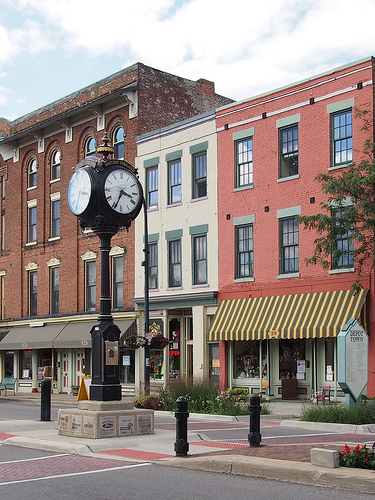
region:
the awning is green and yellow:
[204, 283, 370, 344]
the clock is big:
[62, 156, 146, 233]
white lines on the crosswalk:
[0, 448, 151, 497]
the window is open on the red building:
[272, 116, 303, 183]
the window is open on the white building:
[186, 144, 210, 201]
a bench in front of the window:
[0, 374, 19, 401]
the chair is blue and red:
[311, 382, 335, 406]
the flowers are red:
[339, 441, 366, 465]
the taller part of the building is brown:
[4, 61, 242, 399]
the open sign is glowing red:
[166, 346, 182, 358]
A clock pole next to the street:
[56, 133, 148, 402]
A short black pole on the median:
[170, 393, 195, 461]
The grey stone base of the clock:
[53, 399, 160, 440]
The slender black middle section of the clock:
[89, 224, 119, 322]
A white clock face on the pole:
[104, 168, 139, 216]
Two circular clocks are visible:
[66, 165, 146, 220]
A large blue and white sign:
[334, 311, 373, 402]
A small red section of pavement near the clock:
[104, 445, 174, 464]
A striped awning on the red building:
[213, 295, 366, 338]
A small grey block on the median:
[308, 445, 347, 469]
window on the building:
[188, 148, 217, 210]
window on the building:
[184, 234, 213, 284]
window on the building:
[159, 241, 183, 286]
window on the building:
[142, 246, 155, 288]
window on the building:
[231, 220, 261, 274]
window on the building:
[279, 219, 302, 272]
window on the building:
[281, 129, 304, 172]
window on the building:
[234, 139, 256, 186]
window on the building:
[167, 163, 183, 214]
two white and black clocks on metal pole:
[66, 164, 145, 226]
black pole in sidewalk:
[166, 391, 199, 463]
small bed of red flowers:
[334, 436, 374, 475]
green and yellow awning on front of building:
[204, 284, 370, 345]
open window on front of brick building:
[268, 117, 311, 187]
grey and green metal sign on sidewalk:
[329, 307, 374, 406]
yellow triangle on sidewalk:
[67, 372, 92, 403]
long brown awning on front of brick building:
[1, 312, 139, 351]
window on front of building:
[138, 314, 188, 383]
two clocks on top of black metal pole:
[59, 128, 143, 406]